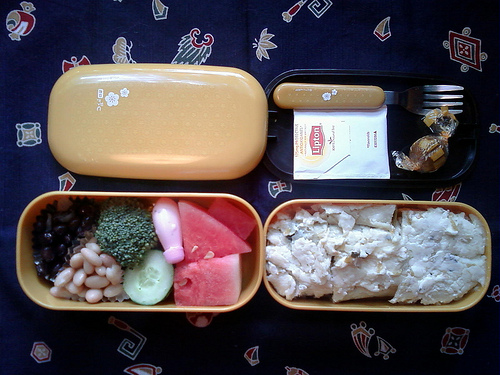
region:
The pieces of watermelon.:
[178, 197, 248, 313]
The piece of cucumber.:
[119, 253, 175, 303]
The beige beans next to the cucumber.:
[49, 249, 122, 300]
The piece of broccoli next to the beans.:
[99, 201, 156, 266]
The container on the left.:
[15, 187, 262, 309]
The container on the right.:
[260, 195, 492, 313]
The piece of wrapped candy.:
[396, 112, 453, 174]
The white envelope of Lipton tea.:
[291, 109, 392, 180]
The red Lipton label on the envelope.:
[309, 121, 324, 155]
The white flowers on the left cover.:
[106, 81, 133, 107]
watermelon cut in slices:
[188, 216, 240, 311]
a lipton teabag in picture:
[281, 116, 400, 177]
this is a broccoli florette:
[85, 205, 156, 251]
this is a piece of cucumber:
[124, 251, 176, 327]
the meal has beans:
[39, 241, 146, 335]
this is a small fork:
[261, 66, 494, 112]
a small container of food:
[23, 181, 223, 318]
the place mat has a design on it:
[7, 22, 99, 78]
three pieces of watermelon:
[181, 191, 266, 342]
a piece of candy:
[390, 110, 472, 182]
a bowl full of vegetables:
[15, 179, 279, 330]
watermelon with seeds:
[171, 196, 249, 320]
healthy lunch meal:
[23, 33, 475, 348]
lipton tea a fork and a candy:
[261, 50, 478, 195]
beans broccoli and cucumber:
[13, 174, 187, 329]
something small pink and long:
[133, 187, 204, 267]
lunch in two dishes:
[22, 28, 485, 360]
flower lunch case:
[24, 27, 285, 181]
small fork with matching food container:
[32, 48, 472, 185]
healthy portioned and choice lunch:
[19, 41, 498, 353]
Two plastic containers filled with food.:
[10, 186, 487, 355]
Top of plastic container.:
[40, 59, 273, 185]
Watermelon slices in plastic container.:
[176, 198, 255, 307]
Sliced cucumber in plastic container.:
[122, 248, 174, 307]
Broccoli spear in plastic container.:
[91, 203, 158, 268]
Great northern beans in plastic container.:
[52, 243, 127, 303]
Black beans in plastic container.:
[26, 206, 78, 268]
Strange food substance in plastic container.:
[277, 211, 478, 306]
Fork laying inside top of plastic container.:
[270, 75, 470, 112]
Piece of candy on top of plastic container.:
[393, 105, 464, 178]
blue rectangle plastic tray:
[262, 66, 482, 176]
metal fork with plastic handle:
[275, 81, 461, 113]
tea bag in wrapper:
[290, 107, 390, 179]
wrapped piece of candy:
[390, 110, 455, 170]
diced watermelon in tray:
[180, 200, 250, 261]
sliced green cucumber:
[121, 250, 168, 300]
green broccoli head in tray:
[95, 197, 150, 264]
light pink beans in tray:
[50, 240, 120, 305]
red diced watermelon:
[171, 255, 238, 305]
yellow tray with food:
[12, 193, 262, 316]